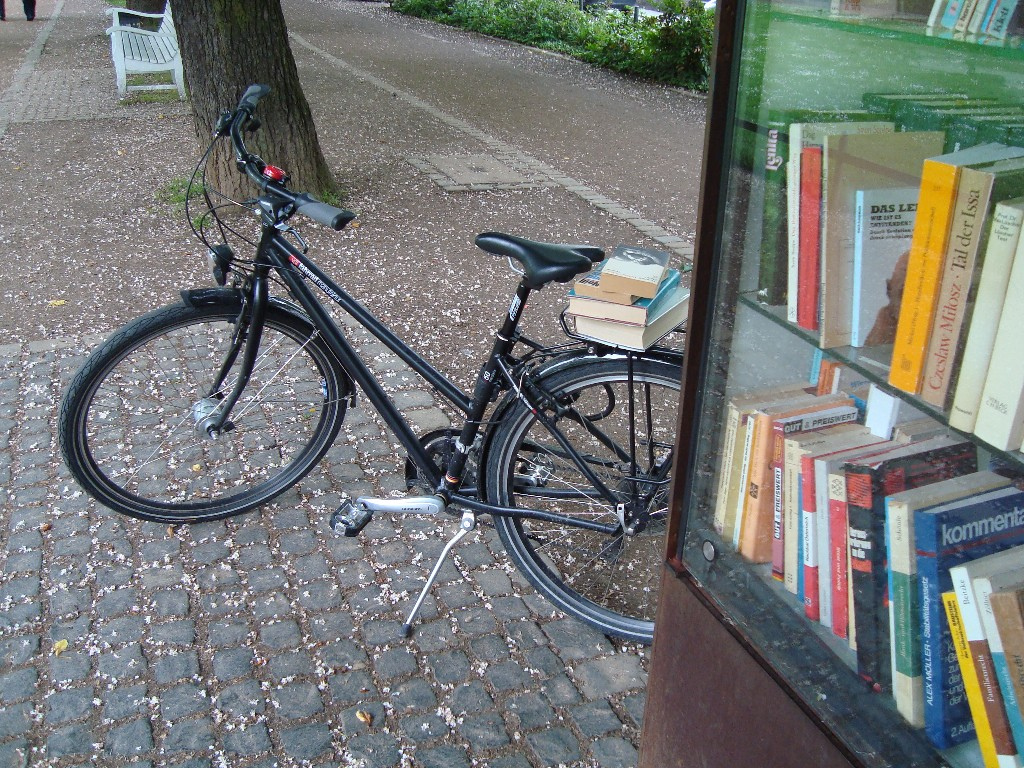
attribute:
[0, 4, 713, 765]
sidewalk — paved, dotted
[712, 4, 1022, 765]
books — selection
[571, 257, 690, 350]
books — stack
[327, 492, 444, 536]
pedal — black, silver, bicycle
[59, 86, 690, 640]
bicycle — parked, red, commuter, black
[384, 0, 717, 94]
hedge — green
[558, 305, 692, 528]
rack — luggage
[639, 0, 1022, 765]
bookshelf — glass, encased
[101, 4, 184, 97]
bench — white, park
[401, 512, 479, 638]
kickstand — rubber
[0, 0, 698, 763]
pathway — stone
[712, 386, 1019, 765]
book — titles, German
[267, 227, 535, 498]
frame — girl's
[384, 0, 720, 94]
bushes — stone